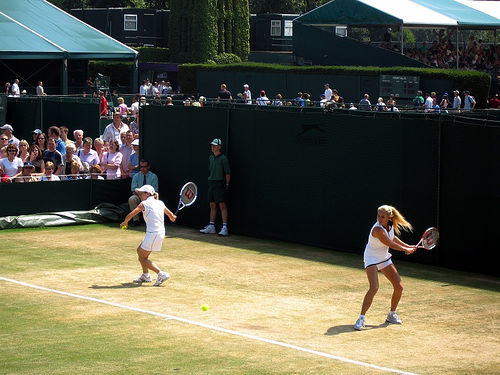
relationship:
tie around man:
[138, 174, 148, 186] [126, 157, 159, 213]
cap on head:
[135, 184, 156, 195] [129, 180, 159, 197]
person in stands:
[462, 90, 476, 111] [111, 73, 499, 138]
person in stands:
[451, 90, 459, 112] [111, 73, 499, 138]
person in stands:
[438, 94, 449, 111] [111, 73, 499, 138]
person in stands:
[424, 91, 436, 113] [111, 73, 499, 138]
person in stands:
[357, 92, 372, 112] [111, 73, 499, 138]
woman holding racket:
[117, 182, 179, 289] [172, 180, 199, 215]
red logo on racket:
[183, 188, 198, 200] [413, 225, 444, 255]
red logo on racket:
[424, 235, 436, 246] [171, 175, 200, 215]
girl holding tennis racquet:
[350, 203, 417, 331] [408, 223, 442, 251]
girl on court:
[353, 205, 417, 331] [2, 218, 493, 369]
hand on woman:
[403, 239, 420, 256] [352, 199, 412, 324]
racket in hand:
[405, 224, 447, 248] [403, 239, 420, 256]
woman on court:
[117, 182, 179, 289] [0, 220, 490, 374]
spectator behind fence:
[60, 142, 84, 179] [261, 132, 351, 192]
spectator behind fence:
[101, 138, 121, 179] [261, 132, 351, 192]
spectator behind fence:
[0, 142, 24, 179] [261, 132, 351, 192]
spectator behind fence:
[43, 139, 60, 172] [261, 132, 351, 192]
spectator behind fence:
[106, 107, 129, 149] [261, 132, 351, 192]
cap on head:
[135, 184, 156, 195] [136, 182, 152, 198]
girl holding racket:
[353, 205, 417, 331] [405, 227, 440, 255]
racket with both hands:
[405, 227, 440, 255] [403, 238, 416, 262]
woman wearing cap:
[117, 182, 179, 289] [131, 179, 159, 198]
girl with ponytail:
[353, 205, 417, 331] [390, 205, 411, 235]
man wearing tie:
[130, 155, 160, 222] [140, 169, 149, 189]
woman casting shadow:
[117, 182, 179, 289] [88, 276, 157, 293]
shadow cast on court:
[88, 276, 157, 293] [2, 180, 488, 370]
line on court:
[105, 297, 312, 358] [2, 218, 493, 369]